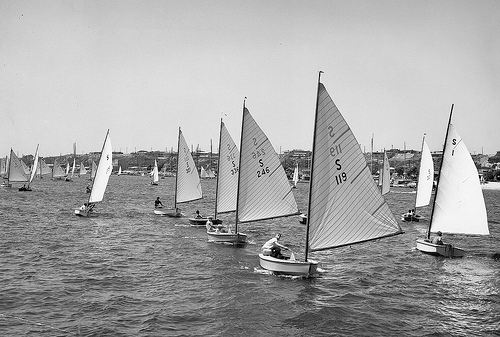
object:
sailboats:
[19, 144, 40, 192]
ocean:
[162, 294, 253, 323]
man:
[261, 232, 290, 259]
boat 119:
[256, 70, 404, 280]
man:
[206, 216, 220, 232]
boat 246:
[205, 95, 301, 248]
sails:
[175, 126, 203, 204]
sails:
[414, 133, 434, 209]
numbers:
[335, 172, 347, 185]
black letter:
[451, 138, 463, 156]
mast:
[304, 71, 324, 262]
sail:
[429, 123, 492, 236]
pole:
[426, 103, 455, 241]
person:
[154, 196, 164, 208]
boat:
[154, 126, 203, 217]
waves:
[44, 243, 124, 318]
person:
[79, 203, 88, 213]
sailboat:
[75, 128, 114, 216]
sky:
[198, 28, 275, 59]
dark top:
[155, 203, 165, 209]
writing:
[257, 166, 271, 177]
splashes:
[251, 266, 274, 277]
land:
[117, 150, 152, 164]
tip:
[317, 70, 324, 83]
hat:
[437, 231, 443, 236]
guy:
[432, 231, 445, 246]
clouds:
[364, 39, 425, 63]